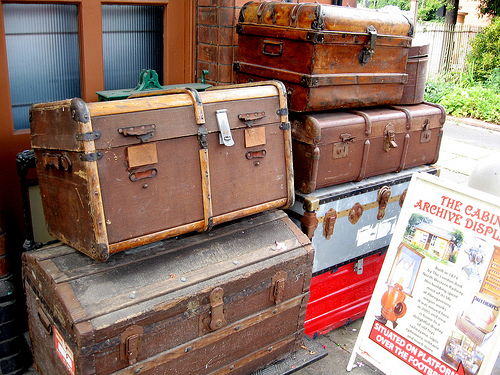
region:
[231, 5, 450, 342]
the suitcases are stacked.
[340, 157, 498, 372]
the sign is white.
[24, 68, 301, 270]
the suitcase is brown.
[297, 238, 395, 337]
the suitcase is red.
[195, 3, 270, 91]
the building is brick.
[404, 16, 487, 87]
the fence is wooden.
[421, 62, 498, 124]
the plants are green.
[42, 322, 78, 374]
the tag is red and white.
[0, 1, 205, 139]
the door is wooden.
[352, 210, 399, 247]
the sticker is white and falling off.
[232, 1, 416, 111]
wood chest with brass accents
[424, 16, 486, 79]
fence along the yard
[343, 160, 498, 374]
a colorful sandwich board ad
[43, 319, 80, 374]
red tag on wooden trunk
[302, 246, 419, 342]
bright red metal trunk with steel lock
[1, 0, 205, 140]
rippled glass panes in a door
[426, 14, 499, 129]
green vegetation across yard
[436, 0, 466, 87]
base of a tree outside fence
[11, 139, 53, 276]
handle of a trunk trolly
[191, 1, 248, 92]
buildings red brick around doorway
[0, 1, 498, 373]
outdoor area with stacked trunks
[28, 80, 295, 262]
top left antique trunk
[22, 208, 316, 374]
bottom left antique trunk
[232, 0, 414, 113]
topmost right antique trunk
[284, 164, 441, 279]
silver and black antique trunk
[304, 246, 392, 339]
red and black antique trunk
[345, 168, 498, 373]
white sign advertising display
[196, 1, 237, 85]
brick wall behind trunk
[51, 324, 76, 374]
red and white sticker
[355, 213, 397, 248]
ripped white sticker on trunk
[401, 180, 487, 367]
Advertising sign with words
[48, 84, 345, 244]
Old fashioned brown trunk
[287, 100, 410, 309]
Multiple colored trunks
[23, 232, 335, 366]
Large beat-up trunk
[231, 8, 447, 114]
Brownish rounded smaller trunk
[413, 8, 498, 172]
Sunny day with trees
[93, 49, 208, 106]
Green material on trunk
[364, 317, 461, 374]
Arrow with words pointing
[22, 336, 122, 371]
Red and white label on trunk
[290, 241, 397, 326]
Bright red trunk on ground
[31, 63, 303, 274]
a brown trunk on another trunk.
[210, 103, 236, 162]
a tag on a brown trunk.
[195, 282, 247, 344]
a latch on a trunk.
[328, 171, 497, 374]
a bill board near trunks.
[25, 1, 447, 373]
a stack of brown trunks.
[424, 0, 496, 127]
a cluster of green plant growth.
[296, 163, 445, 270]
a blue trunk with latches.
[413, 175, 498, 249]
red writing on a billboard.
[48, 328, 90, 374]
a tag on the side of a trunk.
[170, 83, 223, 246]
the center of a trunk.